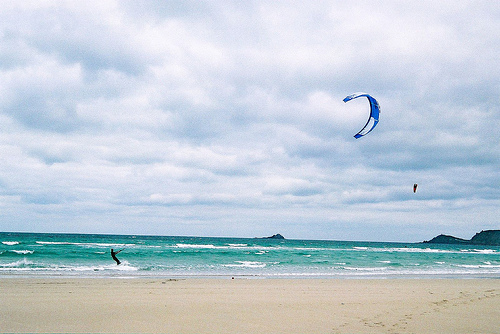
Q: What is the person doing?
A: Parasailing.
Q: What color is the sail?
A: Blue, white.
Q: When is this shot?
A: Daytime.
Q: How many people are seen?
A: 1.